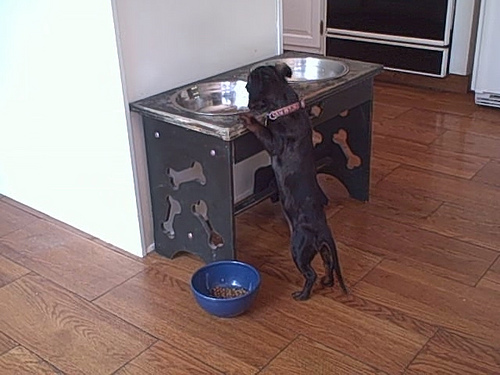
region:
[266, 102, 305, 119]
The collar around the dog's neck.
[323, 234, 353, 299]
The tail of the dog standing up.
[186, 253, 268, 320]
The blue bowl on the floor.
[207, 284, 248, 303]
The food inside of the blue bowl.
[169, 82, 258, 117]
The silver bowl the dog is looking into.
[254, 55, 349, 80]
The silver bowl on the right of the stand.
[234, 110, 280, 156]
The dog's left arm on the silver and black stand.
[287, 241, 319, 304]
The dog's back left leg.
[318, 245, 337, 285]
The dog's back right leg.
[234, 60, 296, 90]
The ears of the dog standing up.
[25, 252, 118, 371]
this is the floor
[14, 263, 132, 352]
the floor is wooden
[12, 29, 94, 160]
this is the wall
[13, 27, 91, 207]
the wall is white in color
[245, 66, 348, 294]
this is a dog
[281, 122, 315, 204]
the fur is black in color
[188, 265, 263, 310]
this is a bowl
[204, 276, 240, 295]
the bowl has some food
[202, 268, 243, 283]
the bowl is blue in color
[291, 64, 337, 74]
the area is shiny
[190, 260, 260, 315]
big blue dog bowl on the ground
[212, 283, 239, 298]
dog food in the blue bowl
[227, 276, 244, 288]
reflection in the bowl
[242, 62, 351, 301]
little black dog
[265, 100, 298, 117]
pink dog collar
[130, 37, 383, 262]
tall dog food feeder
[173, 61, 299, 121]
silver dog bowl with a dog looking into it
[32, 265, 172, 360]
part of the wooden floor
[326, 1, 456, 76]
black and white appliance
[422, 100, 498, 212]
reflection on the wooden floor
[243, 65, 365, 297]
this is a dog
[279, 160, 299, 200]
the dog is black in color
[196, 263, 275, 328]
this is a bowl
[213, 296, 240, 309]
the bowl is blue in color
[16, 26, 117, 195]
this is a wall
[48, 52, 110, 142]
the wall is white in color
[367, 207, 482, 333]
this is the floor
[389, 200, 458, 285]
the floor is brown in color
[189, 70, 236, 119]
this is a sink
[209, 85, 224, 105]
the sink is shinny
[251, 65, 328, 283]
the dog is standing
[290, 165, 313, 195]
the dog is black in color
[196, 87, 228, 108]
this is a sink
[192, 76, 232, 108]
the sink is silvery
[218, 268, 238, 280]
the bowl is blue in color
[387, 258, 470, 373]
the floor is wooden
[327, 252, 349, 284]
the tail is short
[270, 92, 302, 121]
this is a red ribbon